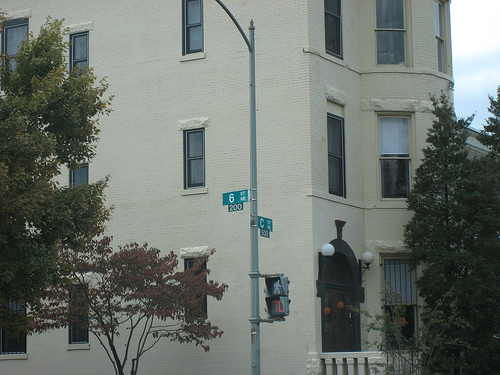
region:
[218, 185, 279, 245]
a few street signs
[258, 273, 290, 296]
a walk sign display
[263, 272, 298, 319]
a traffic sign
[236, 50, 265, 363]
a tall metal street post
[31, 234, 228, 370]
a tree with fall foliage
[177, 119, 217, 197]
a two part window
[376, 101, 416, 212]
a window with half closed blinds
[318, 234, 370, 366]
a curved door way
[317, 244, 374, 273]
a pair of porch lights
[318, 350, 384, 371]
a few stone pillars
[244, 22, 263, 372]
a street pole is on the street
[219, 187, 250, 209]
a sign is on the pole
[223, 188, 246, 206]
the sign has lettering on it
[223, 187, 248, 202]
the lettering is white in color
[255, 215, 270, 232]
the lettering is white in color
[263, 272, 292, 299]
a traffic sign is on the pole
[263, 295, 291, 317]
a traffic sign is on the pole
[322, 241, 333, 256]
a light globe is on the entrance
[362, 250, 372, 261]
a light globe is on the entrance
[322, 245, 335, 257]
the light globe is white in color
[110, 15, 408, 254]
this is a building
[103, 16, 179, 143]
this is the wall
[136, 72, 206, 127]
the wall is white in color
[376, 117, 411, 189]
this is a window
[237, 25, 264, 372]
this is a pole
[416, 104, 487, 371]
this is a tree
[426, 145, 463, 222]
the leaves are green in color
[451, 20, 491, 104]
this is the sky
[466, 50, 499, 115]
the sky is blue in color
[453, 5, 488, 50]
these are the clouds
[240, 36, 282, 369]
tall grey light pole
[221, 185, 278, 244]
green and white signs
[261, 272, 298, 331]
grey pedestrian walk sign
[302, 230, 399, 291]
white globe lights on doorway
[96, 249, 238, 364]
red blooms on tree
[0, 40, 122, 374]
tall green tree on left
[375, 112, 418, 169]
white blind in window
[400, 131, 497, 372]
evergreen tree right of white blind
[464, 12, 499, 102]
white clouds in sky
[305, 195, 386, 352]
black doorway on building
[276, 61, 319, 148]
this is a building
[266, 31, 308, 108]
this is the wall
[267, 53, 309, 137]
the wall is cream in color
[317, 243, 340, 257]
this is the light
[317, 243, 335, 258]
the bulb is white in color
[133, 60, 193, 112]
the wall is clean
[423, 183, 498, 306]
this is a tree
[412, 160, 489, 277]
the tree is leafy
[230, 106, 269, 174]
this is a pole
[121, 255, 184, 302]
the leaves are dry